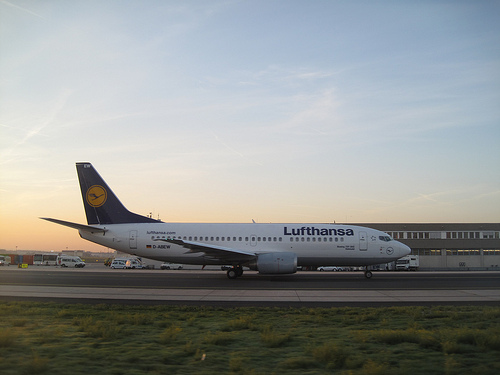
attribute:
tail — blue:
[75, 158, 165, 225]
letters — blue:
[262, 214, 372, 242]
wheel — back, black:
[226, 265, 238, 277]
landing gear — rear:
[225, 267, 237, 277]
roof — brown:
[316, 220, 493, 247]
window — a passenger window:
[340, 235, 347, 242]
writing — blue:
[283, 223, 356, 240]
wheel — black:
[359, 263, 379, 280]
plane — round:
[52, 136, 432, 321]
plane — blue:
[40, 147, 430, 293]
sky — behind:
[2, 1, 498, 248]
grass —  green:
[202, 310, 350, 367]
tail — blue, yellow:
[63, 152, 143, 224]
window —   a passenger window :
[320, 238, 327, 244]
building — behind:
[318, 219, 498, 273]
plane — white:
[46, 160, 413, 287]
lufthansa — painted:
[279, 222, 355, 234]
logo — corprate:
[283, 224, 353, 234]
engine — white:
[254, 252, 297, 277]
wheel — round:
[219, 267, 241, 282]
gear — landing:
[350, 264, 380, 284]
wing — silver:
[159, 230, 269, 271]